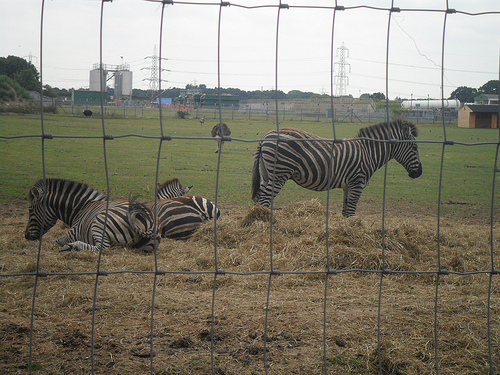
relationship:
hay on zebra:
[0, 201, 498, 373] [145, 172, 225, 242]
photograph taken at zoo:
[7, 0, 499, 371] [1, 0, 498, 367]